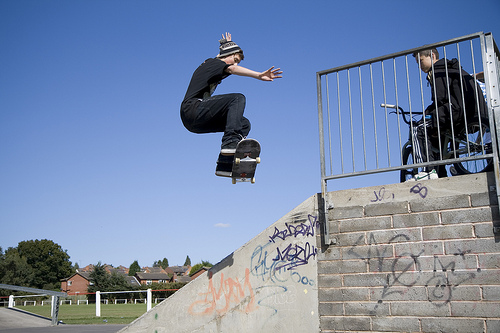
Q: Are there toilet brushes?
A: No, there are no toilet brushes.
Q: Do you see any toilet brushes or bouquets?
A: No, there are no toilet brushes or bouquets.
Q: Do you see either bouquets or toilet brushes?
A: No, there are no toilet brushes or bouquets.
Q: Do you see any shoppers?
A: No, there are no shoppers.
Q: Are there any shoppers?
A: No, there are no shoppers.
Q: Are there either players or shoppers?
A: No, there are no shoppers or players.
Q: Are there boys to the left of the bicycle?
A: Yes, there is a boy to the left of the bicycle.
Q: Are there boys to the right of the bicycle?
A: No, the boy is to the left of the bicycle.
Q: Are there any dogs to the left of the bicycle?
A: No, there is a boy to the left of the bicycle.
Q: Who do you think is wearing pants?
A: The boy is wearing pants.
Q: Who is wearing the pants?
A: The boy is wearing pants.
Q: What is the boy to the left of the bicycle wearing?
A: The boy is wearing trousers.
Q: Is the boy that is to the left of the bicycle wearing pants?
A: Yes, the boy is wearing pants.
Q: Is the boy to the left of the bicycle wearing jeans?
A: No, the boy is wearing pants.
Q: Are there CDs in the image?
A: No, there are no cds.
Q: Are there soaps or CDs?
A: No, there are no CDs or soaps.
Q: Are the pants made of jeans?
A: Yes, the pants are made of jeans.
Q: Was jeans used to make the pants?
A: Yes, the pants are made of jeans.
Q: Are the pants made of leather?
A: No, the pants are made of denim.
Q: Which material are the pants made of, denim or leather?
A: The pants are made of denim.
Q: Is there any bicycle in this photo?
A: Yes, there is a bicycle.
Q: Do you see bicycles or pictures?
A: Yes, there is a bicycle.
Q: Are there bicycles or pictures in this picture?
A: Yes, there is a bicycle.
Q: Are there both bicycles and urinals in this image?
A: No, there is a bicycle but no urinals.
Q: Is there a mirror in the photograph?
A: No, there are no mirrors.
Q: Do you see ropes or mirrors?
A: No, there are no mirrors or ropes.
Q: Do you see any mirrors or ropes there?
A: No, there are no mirrors or ropes.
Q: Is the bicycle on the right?
A: Yes, the bicycle is on the right of the image.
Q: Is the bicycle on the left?
A: No, the bicycle is on the right of the image.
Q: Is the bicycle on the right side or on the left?
A: The bicycle is on the right of the image.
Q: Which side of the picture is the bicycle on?
A: The bicycle is on the right of the image.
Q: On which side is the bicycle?
A: The bicycle is on the right of the image.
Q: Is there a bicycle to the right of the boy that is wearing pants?
A: Yes, there is a bicycle to the right of the boy.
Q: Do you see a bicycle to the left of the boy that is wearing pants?
A: No, the bicycle is to the right of the boy.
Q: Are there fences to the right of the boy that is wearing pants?
A: No, there is a bicycle to the right of the boy.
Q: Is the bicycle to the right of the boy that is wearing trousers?
A: Yes, the bicycle is to the right of the boy.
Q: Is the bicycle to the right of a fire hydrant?
A: No, the bicycle is to the right of the boy.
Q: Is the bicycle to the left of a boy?
A: No, the bicycle is to the right of a boy.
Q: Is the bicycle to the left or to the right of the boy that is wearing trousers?
A: The bicycle is to the right of the boy.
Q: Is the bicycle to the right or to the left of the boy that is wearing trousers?
A: The bicycle is to the right of the boy.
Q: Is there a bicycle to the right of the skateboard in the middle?
A: Yes, there is a bicycle to the right of the skateboard.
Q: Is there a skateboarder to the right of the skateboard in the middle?
A: No, there is a bicycle to the right of the skateboard.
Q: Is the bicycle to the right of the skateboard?
A: Yes, the bicycle is to the right of the skateboard.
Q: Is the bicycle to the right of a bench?
A: No, the bicycle is to the right of the skateboard.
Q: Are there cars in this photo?
A: No, there are no cars.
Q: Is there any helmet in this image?
A: No, there are no helmets.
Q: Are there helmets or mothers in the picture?
A: No, there are no helmets or mothers.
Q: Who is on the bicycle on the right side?
A: The boy is on the bicycle.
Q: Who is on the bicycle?
A: The boy is on the bicycle.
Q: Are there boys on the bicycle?
A: Yes, there is a boy on the bicycle.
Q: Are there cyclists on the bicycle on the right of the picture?
A: No, there is a boy on the bicycle.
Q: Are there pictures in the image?
A: No, there are no pictures.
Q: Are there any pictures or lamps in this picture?
A: No, there are no pictures or lamps.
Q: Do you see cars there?
A: No, there are no cars.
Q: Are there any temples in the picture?
A: No, there are no temples.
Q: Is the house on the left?
A: Yes, the house is on the left of the image.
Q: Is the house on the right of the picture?
A: No, the house is on the left of the image.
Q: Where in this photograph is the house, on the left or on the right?
A: The house is on the left of the image.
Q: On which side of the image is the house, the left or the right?
A: The house is on the left of the image.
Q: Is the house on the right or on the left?
A: The house is on the left of the image.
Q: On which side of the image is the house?
A: The house is on the left of the image.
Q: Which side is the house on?
A: The house is on the left of the image.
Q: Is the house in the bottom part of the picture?
A: Yes, the house is in the bottom of the image.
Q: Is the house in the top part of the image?
A: No, the house is in the bottom of the image.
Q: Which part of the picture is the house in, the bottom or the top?
A: The house is in the bottom of the image.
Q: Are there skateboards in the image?
A: Yes, there is a skateboard.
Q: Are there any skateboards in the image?
A: Yes, there is a skateboard.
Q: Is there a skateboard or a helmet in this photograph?
A: Yes, there is a skateboard.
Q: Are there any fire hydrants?
A: No, there are no fire hydrants.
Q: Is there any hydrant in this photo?
A: No, there are no fire hydrants.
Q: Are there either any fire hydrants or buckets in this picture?
A: No, there are no fire hydrants or buckets.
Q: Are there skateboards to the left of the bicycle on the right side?
A: Yes, there is a skateboard to the left of the bicycle.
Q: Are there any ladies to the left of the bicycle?
A: No, there is a skateboard to the left of the bicycle.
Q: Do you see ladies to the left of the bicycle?
A: No, there is a skateboard to the left of the bicycle.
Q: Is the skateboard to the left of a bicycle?
A: Yes, the skateboard is to the left of a bicycle.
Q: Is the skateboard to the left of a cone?
A: No, the skateboard is to the left of a bicycle.